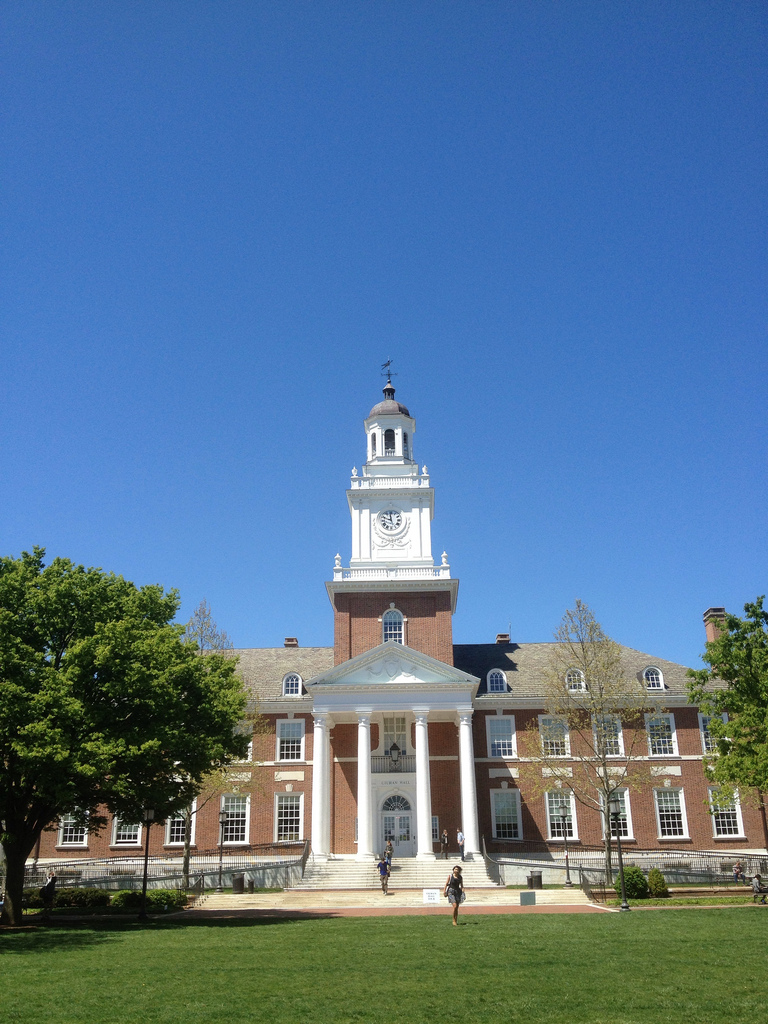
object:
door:
[375, 785, 418, 857]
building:
[0, 351, 768, 890]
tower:
[364, 356, 417, 466]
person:
[444, 866, 466, 926]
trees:
[0, 545, 248, 925]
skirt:
[448, 887, 466, 904]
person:
[457, 824, 466, 862]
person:
[440, 829, 449, 859]